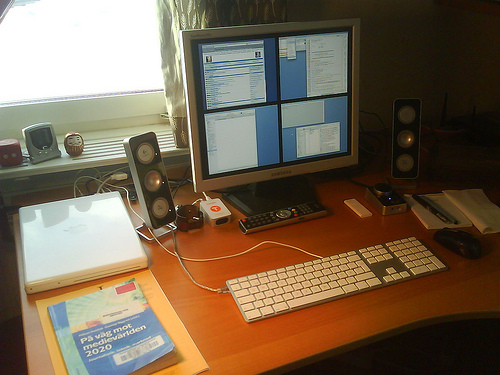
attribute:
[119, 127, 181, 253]
speaker — silver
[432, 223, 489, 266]
computer mouse — black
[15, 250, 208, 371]
folder — yellow 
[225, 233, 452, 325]
keyboard — ultra thin, silver, white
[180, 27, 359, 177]
computer screen — turned on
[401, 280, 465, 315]
desk — wood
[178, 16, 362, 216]
monitor — computer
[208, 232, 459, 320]
keyboard — white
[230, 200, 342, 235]
remote — silver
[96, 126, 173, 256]
speakers — silver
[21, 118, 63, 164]
digital clock — silver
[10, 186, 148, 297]
laptop — white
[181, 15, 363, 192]
screen — square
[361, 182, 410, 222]
camera — silver, digital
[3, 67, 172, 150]
window sill — white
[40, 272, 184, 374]
book — in foreign language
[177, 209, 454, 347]
keyboard — white, silver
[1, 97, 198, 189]
cile — window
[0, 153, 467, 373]
desk — computer